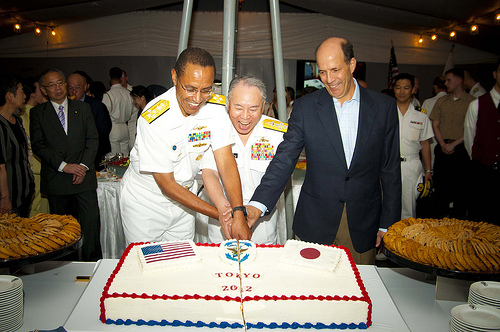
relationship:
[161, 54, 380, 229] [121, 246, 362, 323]
men cutting cake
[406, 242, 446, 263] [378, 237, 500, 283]
cookies on top of tray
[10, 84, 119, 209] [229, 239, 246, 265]
people holding knife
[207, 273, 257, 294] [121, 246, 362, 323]
tokyo 2012 on top of cake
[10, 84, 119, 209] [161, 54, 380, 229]
people standing behind men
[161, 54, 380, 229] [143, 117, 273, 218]
men wearing uniforms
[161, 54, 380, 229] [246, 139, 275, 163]
men have awards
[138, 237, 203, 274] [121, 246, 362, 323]
flag on top of cake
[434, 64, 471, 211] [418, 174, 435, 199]
soldier holding hat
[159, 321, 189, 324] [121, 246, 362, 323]
icing on top of cake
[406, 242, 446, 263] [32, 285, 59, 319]
cookies on top of table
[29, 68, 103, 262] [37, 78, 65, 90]
people wearing glasses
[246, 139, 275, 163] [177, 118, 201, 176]
awards on chest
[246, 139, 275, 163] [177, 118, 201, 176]
awards attached to chest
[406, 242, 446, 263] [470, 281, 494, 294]
cookies on top of plate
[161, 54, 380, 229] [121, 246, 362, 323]
men slicing cake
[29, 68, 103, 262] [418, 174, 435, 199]
people holding hat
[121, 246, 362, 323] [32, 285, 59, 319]
cake on top of table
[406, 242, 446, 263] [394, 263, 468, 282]
cookies on top of tray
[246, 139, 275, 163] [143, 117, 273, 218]
awards on uniforms